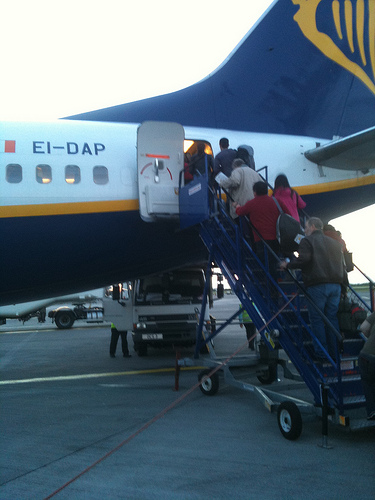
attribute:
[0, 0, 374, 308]
plane — orange, white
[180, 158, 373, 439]
stairs — dark, rolling, blue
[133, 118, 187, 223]
door — open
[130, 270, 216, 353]
truck — white, large, small, van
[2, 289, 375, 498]
tarmac — paved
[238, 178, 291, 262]
person — boarding, walking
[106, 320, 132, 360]
pants — black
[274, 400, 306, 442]
wheel — black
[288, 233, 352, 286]
jacket — tan, green, black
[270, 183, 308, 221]
coat — pink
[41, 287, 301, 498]
cord — red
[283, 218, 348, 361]
man — boarding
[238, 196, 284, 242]
sweater — red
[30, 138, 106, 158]
lettering — blue